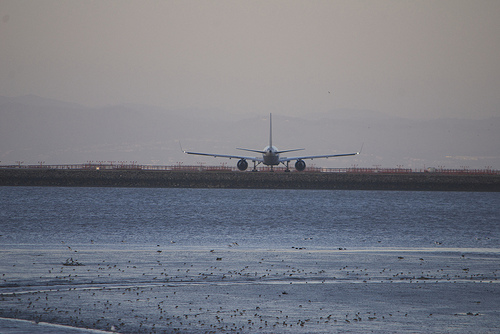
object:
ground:
[0, 170, 500, 192]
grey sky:
[2, 0, 500, 117]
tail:
[270, 113, 273, 149]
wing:
[186, 151, 263, 161]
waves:
[1, 185, 499, 248]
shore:
[0, 247, 500, 334]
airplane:
[180, 113, 364, 172]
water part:
[330, 199, 491, 249]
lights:
[183, 150, 360, 155]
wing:
[280, 153, 355, 162]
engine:
[295, 160, 306, 171]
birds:
[0, 254, 350, 334]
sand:
[216, 297, 393, 328]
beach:
[0, 244, 500, 334]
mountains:
[0, 94, 500, 164]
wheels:
[252, 170, 257, 172]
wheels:
[270, 171, 275, 173]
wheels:
[285, 170, 290, 172]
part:
[286, 211, 320, 223]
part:
[276, 234, 296, 244]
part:
[366, 220, 408, 234]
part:
[388, 194, 406, 211]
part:
[280, 153, 294, 163]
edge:
[0, 315, 109, 334]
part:
[461, 194, 483, 208]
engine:
[237, 159, 248, 171]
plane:
[182, 113, 360, 173]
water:
[0, 182, 500, 248]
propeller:
[295, 160, 306, 170]